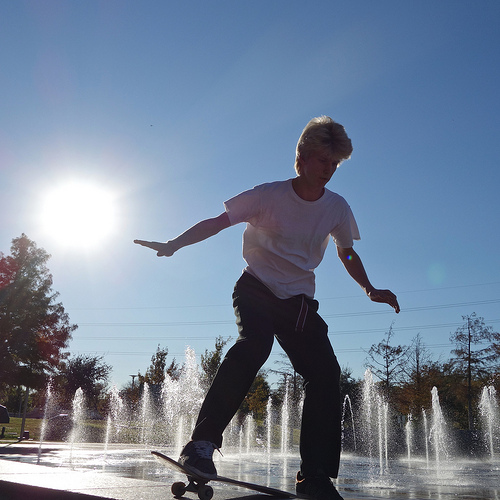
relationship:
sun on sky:
[33, 171, 123, 252] [2, 0, 490, 396]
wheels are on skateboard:
[162, 476, 217, 496] [144, 430, 300, 498]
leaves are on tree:
[0, 250, 67, 386] [0, 236, 83, 411]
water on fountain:
[20, 353, 497, 488] [26, 338, 498, 494]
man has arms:
[135, 115, 401, 499] [128, 185, 408, 321]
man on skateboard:
[135, 115, 401, 499] [126, 105, 415, 497]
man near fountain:
[135, 115, 401, 499] [24, 349, 498, 476]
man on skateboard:
[135, 115, 401, 499] [146, 445, 302, 497]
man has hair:
[135, 115, 401, 499] [293, 113, 354, 158]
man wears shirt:
[135, 115, 401, 499] [224, 180, 363, 300]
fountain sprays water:
[26, 338, 498, 494] [28, 340, 497, 460]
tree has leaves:
[4, 220, 76, 421] [37, 278, 51, 298]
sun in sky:
[33, 171, 123, 252] [8, 69, 197, 296]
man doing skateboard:
[135, 115, 401, 499] [148, 446, 301, 498]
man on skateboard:
[135, 115, 401, 499] [146, 442, 293, 498]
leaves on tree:
[12, 270, 65, 363] [3, 230, 79, 420]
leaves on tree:
[58, 363, 94, 389] [50, 349, 111, 422]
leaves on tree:
[86, 374, 109, 403] [52, 355, 112, 421]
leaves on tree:
[199, 339, 224, 373] [194, 336, 234, 382]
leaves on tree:
[270, 371, 294, 392] [264, 351, 307, 423]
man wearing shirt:
[135, 115, 401, 499] [224, 180, 376, 284]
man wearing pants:
[135, 115, 401, 499] [205, 267, 346, 485]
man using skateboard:
[135, 115, 401, 499] [153, 451, 307, 498]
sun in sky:
[33, 171, 123, 252] [3, 2, 496, 487]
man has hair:
[135, 115, 401, 499] [291, 109, 359, 161]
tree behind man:
[0, 232, 77, 420] [135, 115, 401, 499]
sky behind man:
[2, 0, 490, 396] [135, 115, 401, 499]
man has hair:
[145, 100, 400, 497] [295, 111, 352, 171]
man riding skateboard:
[145, 100, 400, 497] [143, 436, 310, 498]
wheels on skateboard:
[166, 477, 230, 498] [131, 452, 313, 495]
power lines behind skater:
[74, 310, 229, 369] [197, 102, 392, 498]